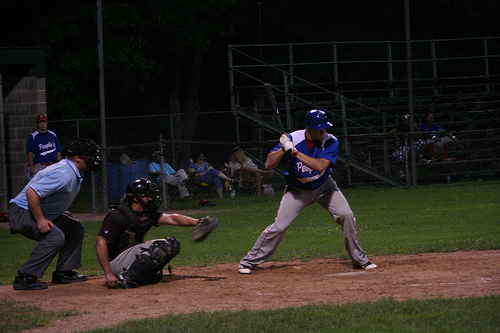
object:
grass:
[0, 183, 500, 332]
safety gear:
[116, 236, 181, 288]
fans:
[386, 113, 458, 166]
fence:
[87, 127, 500, 209]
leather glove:
[191, 213, 218, 243]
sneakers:
[238, 268, 252, 274]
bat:
[263, 82, 296, 166]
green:
[403, 193, 491, 247]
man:
[390, 113, 425, 177]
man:
[187, 152, 239, 199]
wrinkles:
[344, 234, 367, 264]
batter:
[237, 108, 379, 275]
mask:
[64, 136, 106, 169]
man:
[237, 109, 378, 276]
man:
[6, 137, 106, 291]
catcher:
[93, 177, 217, 290]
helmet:
[305, 109, 334, 131]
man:
[24, 115, 63, 180]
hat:
[35, 114, 48, 122]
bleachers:
[218, 42, 499, 184]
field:
[0, 187, 500, 332]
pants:
[237, 179, 370, 268]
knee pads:
[141, 236, 183, 269]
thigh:
[11, 211, 58, 236]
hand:
[37, 219, 55, 235]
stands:
[228, 36, 500, 189]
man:
[95, 176, 219, 290]